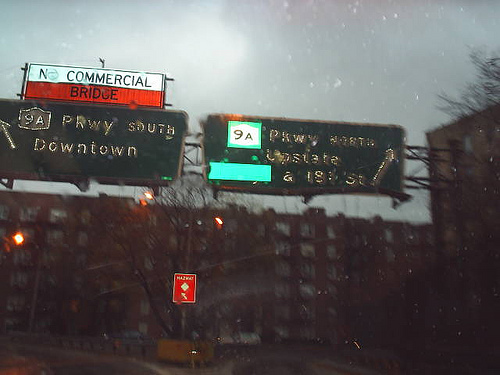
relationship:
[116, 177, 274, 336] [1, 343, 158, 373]
tree near road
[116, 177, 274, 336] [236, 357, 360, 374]
tree near road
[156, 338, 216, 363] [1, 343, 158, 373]
bumper near road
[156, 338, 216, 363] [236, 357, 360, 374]
bumper near road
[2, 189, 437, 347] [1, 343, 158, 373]
housing unit next to road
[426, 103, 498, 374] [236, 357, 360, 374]
housing unit next to road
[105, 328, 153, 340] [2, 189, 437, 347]
car next to housing unit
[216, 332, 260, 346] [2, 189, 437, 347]
car next to housing unit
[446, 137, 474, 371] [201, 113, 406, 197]
post holding sign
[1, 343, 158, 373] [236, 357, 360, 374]
road next to road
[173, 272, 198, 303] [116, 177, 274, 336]
sign near tree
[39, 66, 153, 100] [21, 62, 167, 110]
writing on sign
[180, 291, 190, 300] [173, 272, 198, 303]
arrow on sign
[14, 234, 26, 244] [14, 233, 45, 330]
light on pole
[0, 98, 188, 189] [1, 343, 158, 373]
sign over road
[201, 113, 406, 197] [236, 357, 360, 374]
sign over road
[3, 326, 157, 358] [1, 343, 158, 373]
railing next to road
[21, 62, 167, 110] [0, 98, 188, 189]
sign on top of sign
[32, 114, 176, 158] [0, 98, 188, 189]
letters on sign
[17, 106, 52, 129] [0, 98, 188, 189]
writing on sign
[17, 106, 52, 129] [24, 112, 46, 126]
writing says 9a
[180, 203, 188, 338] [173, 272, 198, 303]
pole supporting sign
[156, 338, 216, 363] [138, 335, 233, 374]
bumper on corner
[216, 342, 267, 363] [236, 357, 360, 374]
railing next to road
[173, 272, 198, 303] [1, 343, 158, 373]
sign in road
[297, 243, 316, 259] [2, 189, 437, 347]
window on housing unit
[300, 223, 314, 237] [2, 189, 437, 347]
window on housing unit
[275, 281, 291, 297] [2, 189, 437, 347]
window on housing unit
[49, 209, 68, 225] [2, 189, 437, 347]
window on housing unit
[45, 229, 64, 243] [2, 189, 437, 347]
window on housing unit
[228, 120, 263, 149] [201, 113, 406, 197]
patch on sign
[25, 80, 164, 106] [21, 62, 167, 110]
orange on sign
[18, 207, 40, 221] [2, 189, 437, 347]
window on housing unit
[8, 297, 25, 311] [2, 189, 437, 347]
window on housing unit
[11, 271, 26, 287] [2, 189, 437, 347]
window on housing unit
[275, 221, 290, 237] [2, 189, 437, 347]
window on housing unit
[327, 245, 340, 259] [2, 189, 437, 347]
window on housing unit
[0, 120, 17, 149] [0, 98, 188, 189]
arrow on sign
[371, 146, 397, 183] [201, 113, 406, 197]
arrow on sign